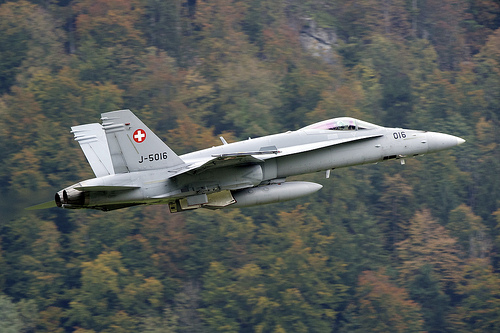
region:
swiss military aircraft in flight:
[43, 103, 467, 219]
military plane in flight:
[45, 101, 469, 226]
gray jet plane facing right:
[51, 98, 473, 235]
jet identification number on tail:
[136, 149, 168, 167]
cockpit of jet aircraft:
[301, 110, 385, 134]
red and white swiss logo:
[130, 127, 149, 147]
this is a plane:
[25, 93, 487, 234]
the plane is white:
[57, 90, 468, 238]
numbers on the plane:
[130, 143, 181, 173]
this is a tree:
[405, 220, 465, 313]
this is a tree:
[348, 252, 419, 322]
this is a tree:
[222, 235, 336, 325]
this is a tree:
[80, 259, 145, 320]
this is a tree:
[355, 35, 469, 135]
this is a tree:
[236, 225, 321, 307]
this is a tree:
[69, 254, 144, 323]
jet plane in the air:
[46, 105, 468, 213]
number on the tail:
[146, 150, 168, 165]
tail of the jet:
[62, 110, 181, 173]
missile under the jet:
[215, 178, 323, 209]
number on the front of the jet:
[393, 130, 410, 140]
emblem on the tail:
[133, 128, 148, 145]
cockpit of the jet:
[304, 113, 376, 133]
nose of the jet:
[433, 126, 466, 151]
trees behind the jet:
[0, 0, 496, 330]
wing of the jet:
[182, 148, 277, 181]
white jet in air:
[56, 83, 472, 218]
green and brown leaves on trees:
[233, 244, 275, 274]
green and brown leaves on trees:
[368, 203, 423, 242]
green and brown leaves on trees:
[400, 239, 450, 274]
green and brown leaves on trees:
[229, 242, 294, 294]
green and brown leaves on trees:
[49, 243, 100, 273]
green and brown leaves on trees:
[372, 24, 438, 64]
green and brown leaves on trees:
[193, 35, 246, 63]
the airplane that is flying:
[54, 106, 466, 213]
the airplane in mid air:
[53, 107, 465, 214]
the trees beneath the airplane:
[1, 0, 499, 331]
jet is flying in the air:
[54, 108, 465, 213]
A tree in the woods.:
[73, 235, 136, 325]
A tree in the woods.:
[191, 252, 226, 331]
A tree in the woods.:
[224, 245, 267, 318]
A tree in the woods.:
[331, 255, 397, 325]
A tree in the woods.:
[388, 200, 438, 297]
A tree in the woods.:
[443, 187, 475, 268]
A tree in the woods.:
[386, 162, 428, 247]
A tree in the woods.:
[388, 65, 473, 214]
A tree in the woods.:
[341, 39, 401, 144]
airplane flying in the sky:
[51, 104, 465, 214]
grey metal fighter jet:
[52, 100, 465, 220]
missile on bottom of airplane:
[215, 175, 323, 207]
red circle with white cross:
[131, 125, 146, 142]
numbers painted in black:
[391, 128, 407, 140]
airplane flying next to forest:
[50, 105, 465, 213]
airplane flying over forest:
[53, 107, 465, 214]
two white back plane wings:
[69, 107, 184, 176]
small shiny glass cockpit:
[297, 115, 380, 135]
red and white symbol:
[132, 127, 147, 144]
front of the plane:
[320, 93, 482, 198]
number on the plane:
[108, 130, 188, 192]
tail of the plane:
[23, 85, 210, 234]